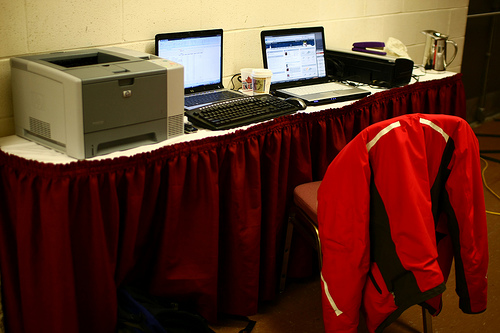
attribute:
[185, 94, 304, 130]
keyboard — black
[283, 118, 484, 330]
chair — red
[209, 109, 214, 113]
key — black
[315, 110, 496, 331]
jacket — red